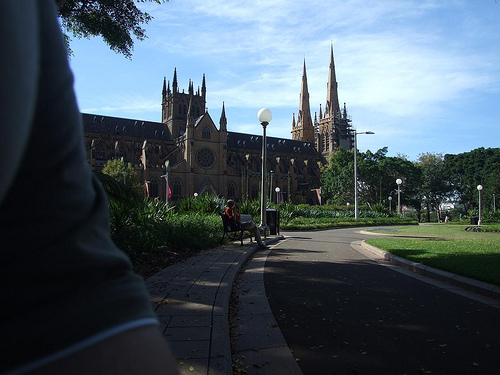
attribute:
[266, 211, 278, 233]
can — trash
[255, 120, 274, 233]
post — lamp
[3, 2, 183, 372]
shirt — gray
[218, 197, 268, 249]
person — sitting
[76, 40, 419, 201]
building — large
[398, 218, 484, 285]
grass — green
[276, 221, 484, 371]
road — dark grey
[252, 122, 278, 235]
pole — light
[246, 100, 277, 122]
lamp — white 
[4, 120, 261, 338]
bushes — green 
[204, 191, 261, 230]
shirt — red 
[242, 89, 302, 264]
lamp — White 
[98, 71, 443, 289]
building — brown , Large 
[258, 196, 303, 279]
trashcan — Black , metal 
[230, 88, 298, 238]
lamp — tall 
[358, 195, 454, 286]
grass — Green 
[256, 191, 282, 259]
wastebasket — Green , small 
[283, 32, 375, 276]
towers — large 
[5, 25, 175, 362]
shirt — gray 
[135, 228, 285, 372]
sidewalk — light grey